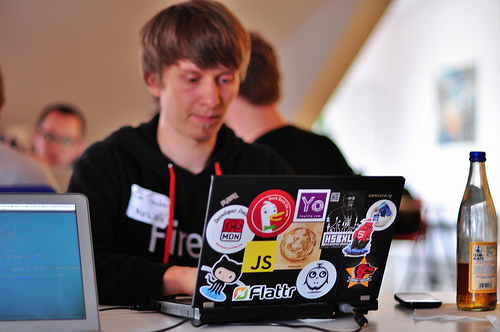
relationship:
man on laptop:
[101, 8, 231, 283] [210, 176, 380, 322]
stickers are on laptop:
[221, 201, 305, 270] [210, 176, 380, 322]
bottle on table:
[449, 161, 491, 312] [407, 317, 439, 327]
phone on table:
[399, 293, 432, 306] [407, 317, 439, 327]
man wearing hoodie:
[101, 8, 231, 283] [97, 232, 144, 260]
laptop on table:
[210, 176, 380, 322] [407, 317, 439, 327]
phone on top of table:
[399, 293, 432, 306] [407, 317, 439, 327]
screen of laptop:
[218, 179, 386, 299] [210, 176, 380, 322]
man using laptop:
[101, 8, 231, 283] [210, 176, 380, 322]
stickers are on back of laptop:
[221, 201, 305, 270] [210, 176, 380, 322]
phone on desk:
[399, 293, 432, 306] [105, 307, 130, 320]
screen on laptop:
[218, 179, 386, 299] [210, 176, 380, 322]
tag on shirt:
[127, 186, 167, 225] [169, 179, 203, 195]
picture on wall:
[426, 62, 481, 144] [357, 89, 395, 122]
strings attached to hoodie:
[160, 166, 180, 197] [97, 232, 144, 260]